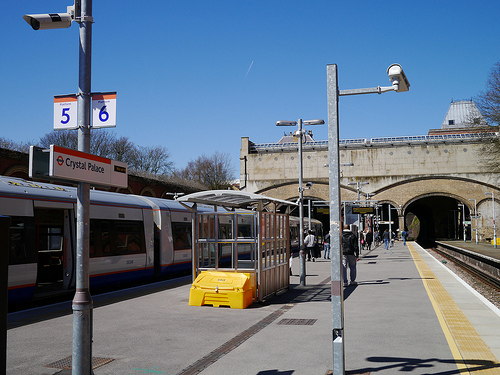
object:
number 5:
[59, 107, 71, 125]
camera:
[293, 129, 308, 138]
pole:
[296, 118, 306, 282]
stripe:
[51, 144, 112, 165]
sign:
[28, 91, 130, 190]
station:
[0, 146, 499, 374]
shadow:
[362, 356, 500, 373]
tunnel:
[402, 191, 472, 240]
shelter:
[173, 189, 301, 306]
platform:
[52, 92, 77, 130]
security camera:
[384, 62, 411, 93]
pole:
[71, 2, 94, 375]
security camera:
[22, 12, 73, 31]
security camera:
[293, 130, 307, 138]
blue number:
[98, 105, 110, 122]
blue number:
[60, 107, 71, 124]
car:
[289, 216, 325, 253]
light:
[384, 62, 409, 94]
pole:
[327, 63, 349, 374]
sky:
[4, 0, 498, 174]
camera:
[386, 63, 411, 93]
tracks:
[440, 240, 496, 282]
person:
[303, 229, 323, 262]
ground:
[5, 239, 498, 374]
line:
[403, 237, 499, 374]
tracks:
[0, 271, 149, 323]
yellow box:
[188, 270, 258, 309]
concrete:
[2, 242, 499, 375]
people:
[353, 222, 413, 252]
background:
[90, 91, 116, 127]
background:
[52, 92, 78, 130]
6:
[98, 105, 109, 122]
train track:
[401, 240, 500, 308]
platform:
[5, 238, 495, 375]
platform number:
[51, 90, 116, 131]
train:
[0, 172, 324, 316]